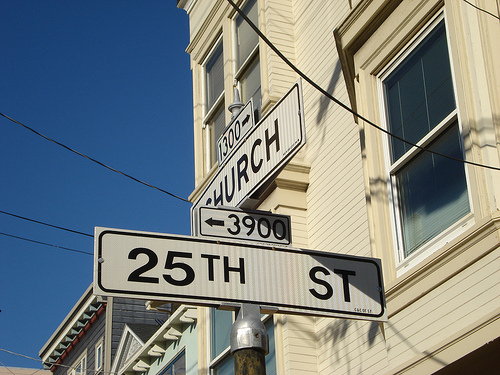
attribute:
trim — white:
[380, 206, 486, 273]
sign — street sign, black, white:
[209, 100, 273, 166]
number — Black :
[223, 212, 240, 244]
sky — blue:
[2, 2, 176, 225]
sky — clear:
[3, 3, 195, 232]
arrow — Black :
[201, 217, 228, 230]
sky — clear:
[87, 40, 155, 127]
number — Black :
[119, 242, 211, 301]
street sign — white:
[100, 210, 382, 306]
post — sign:
[233, 350, 269, 371]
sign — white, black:
[156, 79, 321, 232]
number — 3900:
[226, 211, 294, 246]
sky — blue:
[11, 0, 206, 362]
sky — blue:
[0, 14, 181, 365]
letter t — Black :
[196, 248, 221, 285]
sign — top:
[177, 107, 332, 206]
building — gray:
[37, 282, 171, 373]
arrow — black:
[201, 214, 228, 232]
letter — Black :
[309, 261, 334, 302]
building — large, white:
[182, 43, 496, 371]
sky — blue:
[0, 0, 195, 366]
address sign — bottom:
[91, 225, 386, 321]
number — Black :
[226, 212, 289, 240]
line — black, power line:
[24, 107, 364, 313]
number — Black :
[256, 212, 273, 244]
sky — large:
[3, 13, 184, 312]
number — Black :
[95, 247, 312, 294]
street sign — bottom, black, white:
[88, 225, 390, 333]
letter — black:
[219, 253, 248, 287]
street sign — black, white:
[193, 205, 295, 245]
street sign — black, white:
[187, 74, 304, 232]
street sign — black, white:
[216, 99, 253, 166]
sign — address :
[89, 97, 411, 308]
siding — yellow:
[279, 24, 376, 245]